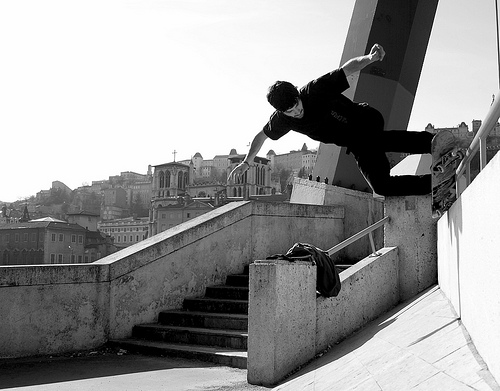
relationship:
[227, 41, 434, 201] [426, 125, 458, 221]
man on skateboard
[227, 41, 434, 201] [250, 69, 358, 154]
man in shirt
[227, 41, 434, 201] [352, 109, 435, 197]
man in pants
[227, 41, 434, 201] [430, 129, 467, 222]
man on skateboard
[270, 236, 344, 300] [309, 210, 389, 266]
clothes laying on rail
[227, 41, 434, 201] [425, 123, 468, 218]
man balancing skateboard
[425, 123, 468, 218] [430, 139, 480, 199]
skateboard on rail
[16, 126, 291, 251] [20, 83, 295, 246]
buildings in skyline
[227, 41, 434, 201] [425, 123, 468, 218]
man doing skateboard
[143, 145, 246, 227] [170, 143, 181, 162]
building with cross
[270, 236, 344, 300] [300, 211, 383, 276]
clothes hanging over a rail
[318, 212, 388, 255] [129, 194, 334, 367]
rail near stairs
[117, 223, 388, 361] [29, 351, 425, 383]
stairs leading down to surface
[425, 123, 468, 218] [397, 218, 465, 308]
skateboard in air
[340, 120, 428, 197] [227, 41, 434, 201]
left leg of man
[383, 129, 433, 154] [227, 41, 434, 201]
right leg of man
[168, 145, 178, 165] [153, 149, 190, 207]
cross on top of building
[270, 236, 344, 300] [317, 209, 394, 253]
clothes on rail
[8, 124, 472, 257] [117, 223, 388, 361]
city beyond stairs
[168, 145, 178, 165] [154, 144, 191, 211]
cross on top of building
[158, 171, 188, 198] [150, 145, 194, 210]
arches in building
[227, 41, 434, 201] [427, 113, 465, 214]
man on skateboard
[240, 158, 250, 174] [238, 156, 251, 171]
watch on wrist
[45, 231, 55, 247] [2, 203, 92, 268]
window on building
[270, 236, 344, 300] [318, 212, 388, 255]
clothes on rail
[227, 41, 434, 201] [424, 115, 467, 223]
man on skateboard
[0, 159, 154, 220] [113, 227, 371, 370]
buildings behind stairs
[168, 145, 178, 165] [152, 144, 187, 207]
cross on top of building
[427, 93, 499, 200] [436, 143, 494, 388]
rail on top of wall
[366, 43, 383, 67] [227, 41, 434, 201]
hand of man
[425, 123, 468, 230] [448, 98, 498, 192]
skateboard sliding on railing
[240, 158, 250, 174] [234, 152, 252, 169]
watch on man's wrist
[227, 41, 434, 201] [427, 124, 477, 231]
man on skateboard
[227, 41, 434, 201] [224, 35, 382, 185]
man has arms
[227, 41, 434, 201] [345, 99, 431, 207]
man wearing pants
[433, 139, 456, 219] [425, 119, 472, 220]
graffiti on bottom of skateboard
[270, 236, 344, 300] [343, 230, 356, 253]
clothes draped on rail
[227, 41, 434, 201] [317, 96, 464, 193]
man doing trick